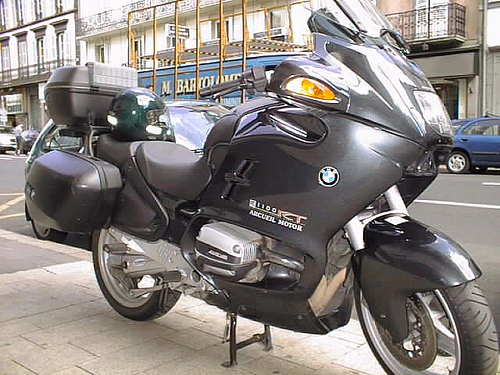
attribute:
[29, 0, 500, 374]
motorcycle — black, bmw, metal, parked, grey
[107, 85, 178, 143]
helmet — green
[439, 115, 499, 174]
car — blue, parked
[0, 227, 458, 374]
sidewalk — brick, cobblestone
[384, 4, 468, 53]
balcony — black, wrought-iron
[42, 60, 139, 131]
storage compartment — black, grey, hard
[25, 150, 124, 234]
storage compartment — black, hard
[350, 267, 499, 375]
wheel — black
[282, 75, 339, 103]
light — yellow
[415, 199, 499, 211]
line — white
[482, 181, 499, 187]
line — white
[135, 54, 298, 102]
sign — blue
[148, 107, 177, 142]
face mask — clear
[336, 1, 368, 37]
wiper — black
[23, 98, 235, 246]
car — green, parked